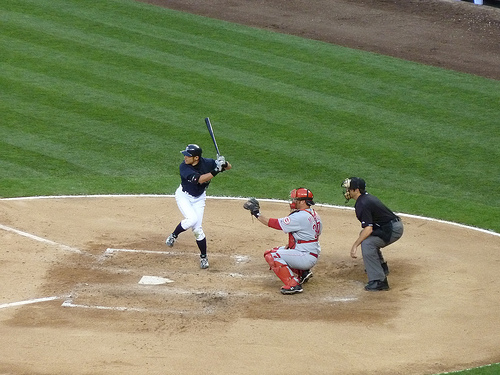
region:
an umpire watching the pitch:
[337, 170, 407, 293]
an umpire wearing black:
[337, 170, 406, 297]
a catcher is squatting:
[241, 185, 328, 296]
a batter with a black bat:
[165, 110, 233, 270]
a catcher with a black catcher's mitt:
[240, 190, 265, 220]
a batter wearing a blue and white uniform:
[162, 110, 234, 277]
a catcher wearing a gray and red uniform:
[243, 183, 326, 298]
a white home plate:
[134, 267, 176, 289]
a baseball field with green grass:
[0, 0, 498, 372]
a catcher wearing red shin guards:
[259, 243, 307, 298]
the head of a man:
[174, 115, 231, 172]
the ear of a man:
[188, 137, 218, 169]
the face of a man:
[174, 148, 203, 185]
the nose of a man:
[171, 136, 206, 167]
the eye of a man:
[174, 135, 213, 170]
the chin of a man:
[173, 131, 207, 173]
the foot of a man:
[157, 218, 193, 259]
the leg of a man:
[159, 173, 205, 256]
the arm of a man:
[174, 164, 226, 193]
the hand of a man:
[207, 134, 247, 179]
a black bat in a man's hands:
[202, 113, 223, 156]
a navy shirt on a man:
[180, 155, 217, 197]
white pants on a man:
[174, 184, 205, 241]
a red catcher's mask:
[288, 185, 313, 213]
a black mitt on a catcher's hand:
[242, 196, 260, 219]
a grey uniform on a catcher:
[278, 208, 322, 268]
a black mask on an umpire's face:
[340, 174, 364, 201]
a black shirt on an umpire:
[353, 192, 395, 224]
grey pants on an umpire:
[359, 217, 405, 280]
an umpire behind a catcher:
[340, 174, 404, 291]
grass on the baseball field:
[11, 5, 474, 197]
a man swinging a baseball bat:
[172, 114, 226, 261]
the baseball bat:
[204, 115, 219, 152]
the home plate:
[138, 273, 170, 289]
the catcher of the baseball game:
[248, 183, 327, 294]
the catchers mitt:
[245, 200, 255, 212]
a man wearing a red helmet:
[245, 183, 318, 292]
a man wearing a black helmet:
[333, 170, 408, 288]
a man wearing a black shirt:
[336, 171, 403, 297]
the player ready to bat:
[170, 116, 225, 269]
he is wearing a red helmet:
[292, 185, 313, 201]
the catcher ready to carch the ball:
[242, 187, 325, 290]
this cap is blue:
[179, 142, 202, 157]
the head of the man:
[342, 177, 363, 199]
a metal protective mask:
[344, 185, 352, 202]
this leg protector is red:
[267, 251, 295, 288]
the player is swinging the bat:
[172, 108, 227, 261]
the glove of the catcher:
[242, 195, 261, 215]